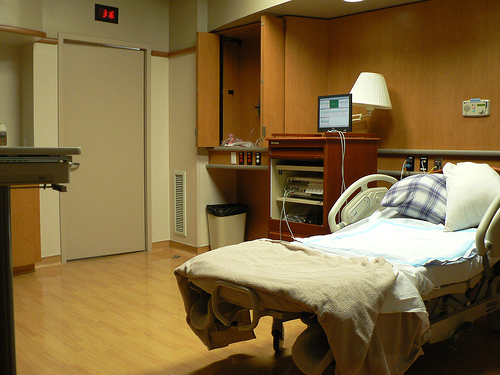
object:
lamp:
[348, 70, 392, 137]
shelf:
[263, 131, 373, 146]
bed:
[172, 172, 499, 374]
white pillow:
[444, 161, 496, 231]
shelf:
[206, 140, 265, 171]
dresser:
[267, 131, 375, 242]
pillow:
[380, 174, 449, 224]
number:
[102, 12, 115, 19]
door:
[62, 35, 148, 255]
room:
[0, 2, 497, 374]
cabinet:
[196, 14, 282, 147]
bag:
[205, 200, 246, 250]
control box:
[460, 95, 490, 117]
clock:
[94, 4, 121, 25]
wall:
[173, 62, 191, 168]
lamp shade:
[348, 70, 396, 112]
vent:
[169, 171, 187, 240]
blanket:
[173, 238, 433, 373]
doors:
[193, 14, 283, 156]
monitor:
[316, 95, 350, 137]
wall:
[118, 63, 196, 244]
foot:
[173, 240, 363, 366]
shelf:
[273, 104, 363, 168]